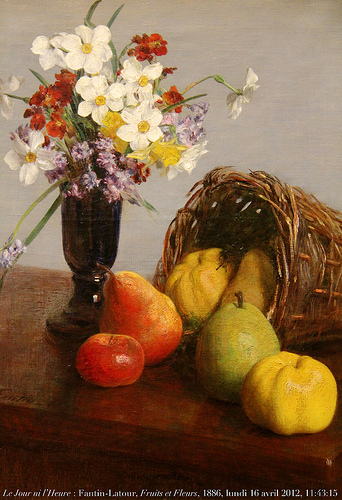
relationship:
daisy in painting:
[0, 25, 260, 186] [0, 0, 342, 500]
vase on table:
[44, 180, 125, 340] [0, 260, 341, 498]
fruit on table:
[75, 247, 337, 435] [6, 263, 64, 348]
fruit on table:
[75, 247, 337, 435] [57, 375, 217, 495]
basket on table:
[153, 164, 340, 345] [0, 260, 341, 498]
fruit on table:
[75, 247, 337, 435] [4, 311, 88, 430]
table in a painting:
[3, 265, 340, 446] [7, 5, 332, 481]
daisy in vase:
[0, 25, 260, 186] [50, 174, 132, 353]